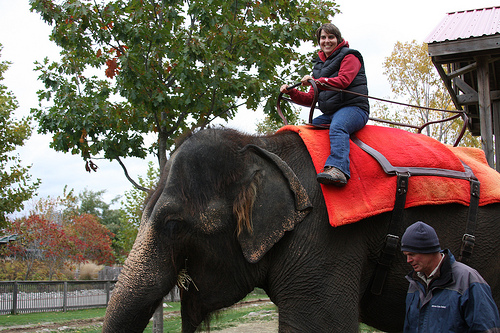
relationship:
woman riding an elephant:
[313, 25, 343, 59] [109, 149, 332, 321]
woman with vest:
[313, 25, 343, 59] [309, 63, 349, 112]